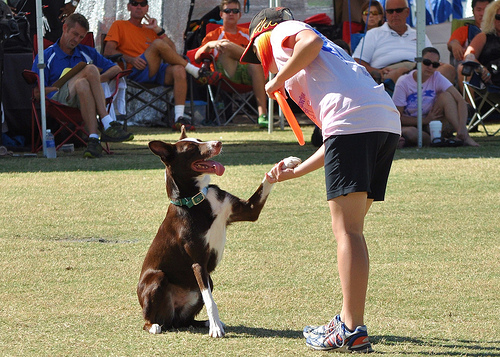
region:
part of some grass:
[401, 243, 481, 307]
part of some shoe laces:
[326, 324, 339, 336]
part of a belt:
[188, 199, 198, 208]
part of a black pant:
[341, 156, 370, 192]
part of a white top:
[345, 107, 385, 128]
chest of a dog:
[200, 203, 224, 244]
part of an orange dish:
[279, 97, 307, 131]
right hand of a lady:
[275, 167, 297, 187]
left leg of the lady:
[331, 242, 368, 279]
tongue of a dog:
[213, 161, 227, 174]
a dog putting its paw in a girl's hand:
[135, 121, 297, 341]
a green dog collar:
[161, 183, 212, 209]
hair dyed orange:
[253, 39, 279, 77]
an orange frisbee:
[268, 87, 308, 148]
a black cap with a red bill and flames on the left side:
[237, 9, 292, 61]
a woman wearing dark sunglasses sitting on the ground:
[398, 41, 471, 153]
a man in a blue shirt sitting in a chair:
[41, 11, 131, 163]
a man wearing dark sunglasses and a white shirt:
[376, 0, 430, 62]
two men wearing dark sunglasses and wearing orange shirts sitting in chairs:
[103, 1, 272, 125]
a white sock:
[101, 113, 111, 127]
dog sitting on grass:
[121, 122, 263, 342]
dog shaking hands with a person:
[127, 3, 393, 349]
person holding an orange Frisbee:
[265, 62, 310, 157]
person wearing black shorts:
[315, 120, 397, 200]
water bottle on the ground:
[33, 122, 61, 172]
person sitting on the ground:
[390, 42, 478, 172]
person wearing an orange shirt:
[103, 0, 168, 60]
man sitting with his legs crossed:
[43, 17, 126, 154]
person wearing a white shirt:
[350, 6, 431, 69]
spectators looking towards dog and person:
[3, 3, 498, 208]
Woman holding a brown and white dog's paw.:
[135, 6, 402, 354]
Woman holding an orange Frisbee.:
[237, 18, 402, 145]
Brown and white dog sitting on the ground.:
[137, 122, 300, 340]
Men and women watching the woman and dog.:
[1, 1, 498, 149]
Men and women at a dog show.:
[1, 1, 497, 355]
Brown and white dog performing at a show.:
[135, 7, 402, 355]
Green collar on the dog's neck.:
[163, 186, 220, 207]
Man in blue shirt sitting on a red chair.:
[25, 13, 133, 160]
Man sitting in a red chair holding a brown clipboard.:
[27, 13, 134, 158]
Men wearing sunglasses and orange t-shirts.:
[105, 1, 275, 128]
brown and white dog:
[135, 123, 299, 336]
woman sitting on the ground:
[391, 46, 479, 148]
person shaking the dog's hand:
[238, 5, 404, 350]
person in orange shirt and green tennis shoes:
[194, 1, 280, 128]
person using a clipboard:
[33, 11, 134, 157]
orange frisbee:
[272, 90, 304, 145]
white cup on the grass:
[428, 118, 441, 146]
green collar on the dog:
[170, 183, 207, 211]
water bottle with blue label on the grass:
[44, 127, 56, 161]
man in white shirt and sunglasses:
[352, 0, 454, 84]